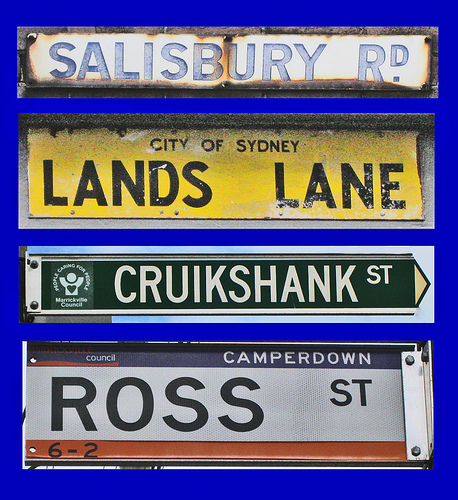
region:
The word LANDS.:
[41, 160, 210, 209]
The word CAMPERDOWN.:
[222, 350, 371, 367]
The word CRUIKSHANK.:
[111, 262, 358, 303]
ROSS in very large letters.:
[52, 373, 265, 433]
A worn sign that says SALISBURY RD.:
[15, 24, 439, 97]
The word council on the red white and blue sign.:
[84, 353, 116, 361]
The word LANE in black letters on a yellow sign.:
[272, 161, 407, 209]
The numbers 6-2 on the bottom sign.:
[47, 439, 99, 457]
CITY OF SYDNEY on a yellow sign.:
[149, 136, 298, 154]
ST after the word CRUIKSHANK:
[366, 263, 392, 285]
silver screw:
[391, 348, 438, 382]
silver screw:
[397, 355, 415, 372]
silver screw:
[403, 352, 424, 372]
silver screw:
[390, 351, 418, 373]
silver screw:
[399, 344, 414, 363]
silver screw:
[395, 347, 412, 368]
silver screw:
[399, 343, 420, 384]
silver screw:
[391, 332, 422, 368]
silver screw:
[378, 348, 418, 382]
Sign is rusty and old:
[17, 20, 450, 110]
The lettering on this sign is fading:
[25, 121, 456, 237]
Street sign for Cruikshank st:
[15, 236, 449, 334]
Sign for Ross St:
[15, 342, 436, 462]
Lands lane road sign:
[10, 109, 443, 231]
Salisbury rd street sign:
[15, 24, 455, 121]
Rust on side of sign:
[15, 30, 31, 82]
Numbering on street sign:
[25, 435, 110, 463]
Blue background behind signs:
[259, 474, 302, 498]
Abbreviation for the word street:
[326, 359, 386, 415]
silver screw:
[408, 446, 451, 478]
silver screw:
[400, 439, 421, 462]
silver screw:
[391, 437, 431, 461]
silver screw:
[403, 444, 434, 463]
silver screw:
[396, 430, 448, 474]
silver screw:
[397, 425, 436, 456]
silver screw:
[399, 444, 425, 481]